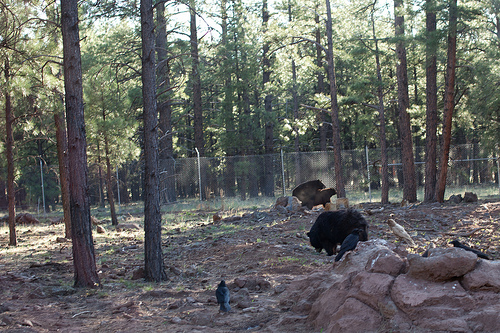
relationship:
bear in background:
[291, 178, 327, 201] [156, 67, 396, 145]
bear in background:
[299, 182, 338, 207] [156, 67, 396, 145]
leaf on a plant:
[93, 32, 116, 73] [232, 100, 272, 161]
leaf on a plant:
[76, 42, 95, 63] [92, 46, 147, 251]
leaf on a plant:
[93, 76, 107, 103] [86, 97, 130, 225]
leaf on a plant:
[78, 43, 100, 58] [83, 44, 132, 199]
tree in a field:
[139, 55, 169, 285] [191, 185, 305, 331]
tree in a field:
[135, 1, 169, 283] [185, 207, 272, 286]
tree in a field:
[392, 25, 404, 190] [364, 169, 474, 231]